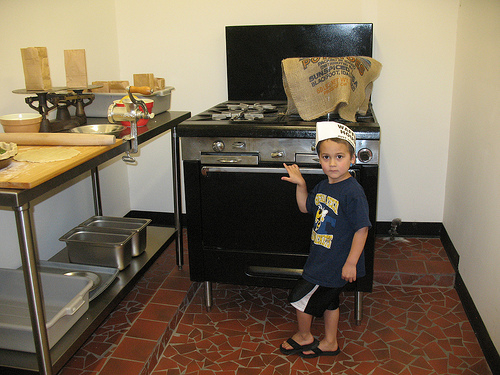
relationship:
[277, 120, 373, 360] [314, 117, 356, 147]
boy wearing hat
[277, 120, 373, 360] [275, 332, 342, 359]
boy wearing flip flops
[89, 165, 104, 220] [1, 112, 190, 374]
leg of table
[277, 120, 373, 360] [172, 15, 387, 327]
boy leaning on oven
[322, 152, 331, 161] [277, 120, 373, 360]
eye of boy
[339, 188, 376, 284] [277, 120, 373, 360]
arm of boy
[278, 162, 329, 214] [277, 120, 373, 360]
arm of boy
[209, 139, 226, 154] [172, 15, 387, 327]
knob on oven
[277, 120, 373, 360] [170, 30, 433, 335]
boy by stove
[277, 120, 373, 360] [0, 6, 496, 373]
boy in kitchen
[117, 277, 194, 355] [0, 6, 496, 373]
step in kitchen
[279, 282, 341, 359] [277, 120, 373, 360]
legs of boy